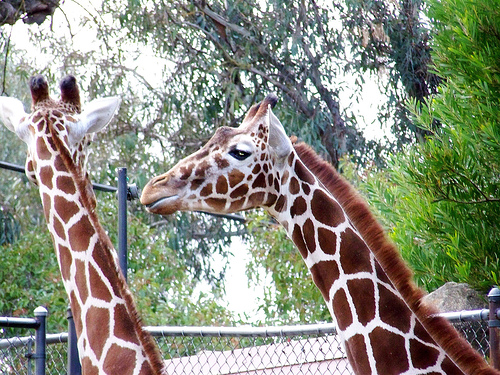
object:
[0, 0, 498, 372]
zoo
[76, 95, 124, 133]
ear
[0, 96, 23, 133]
ear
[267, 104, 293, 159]
ear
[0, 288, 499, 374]
fence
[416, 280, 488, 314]
rock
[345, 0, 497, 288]
green plants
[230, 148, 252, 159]
eye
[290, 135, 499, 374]
mane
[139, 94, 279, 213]
head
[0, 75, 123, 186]
head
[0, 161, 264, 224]
bar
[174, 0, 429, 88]
branches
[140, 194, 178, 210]
mouth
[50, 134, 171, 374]
mane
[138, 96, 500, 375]
giraffe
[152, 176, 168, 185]
nose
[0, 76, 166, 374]
giraffe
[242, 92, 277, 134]
horns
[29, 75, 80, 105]
horns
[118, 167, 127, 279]
pole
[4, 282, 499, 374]
compound